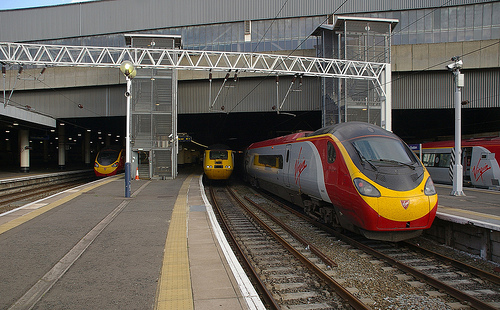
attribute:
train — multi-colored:
[201, 143, 234, 184]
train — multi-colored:
[92, 145, 123, 180]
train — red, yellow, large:
[242, 119, 438, 243]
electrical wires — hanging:
[220, 0, 499, 128]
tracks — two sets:
[0, 176, 499, 309]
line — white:
[198, 171, 265, 309]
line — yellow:
[154, 171, 194, 309]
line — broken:
[241, 193, 337, 269]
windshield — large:
[341, 136, 416, 170]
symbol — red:
[398, 198, 410, 209]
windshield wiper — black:
[350, 141, 416, 171]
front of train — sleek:
[328, 121, 439, 231]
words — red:
[293, 146, 307, 185]